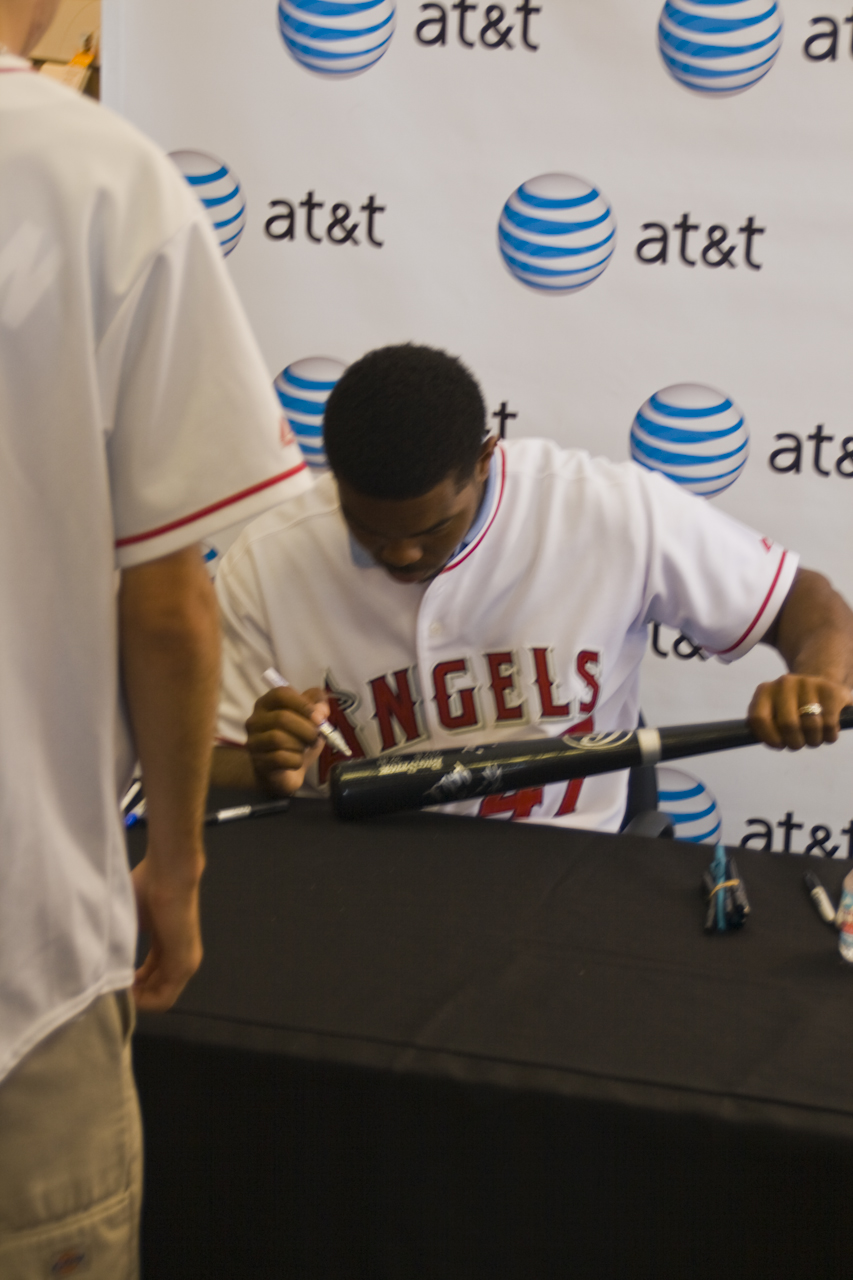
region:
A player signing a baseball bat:
[202, 324, 846, 844]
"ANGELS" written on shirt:
[299, 633, 610, 791]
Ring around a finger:
[784, 681, 832, 729]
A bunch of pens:
[683, 812, 765, 943]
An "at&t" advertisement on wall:
[92, 1, 845, 861]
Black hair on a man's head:
[309, 330, 508, 593]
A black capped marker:
[785, 850, 843, 937]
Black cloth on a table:
[106, 776, 844, 1265]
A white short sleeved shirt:
[0, 37, 326, 1084]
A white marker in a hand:
[229, 648, 366, 810]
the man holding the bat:
[227, 334, 850, 876]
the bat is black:
[314, 680, 850, 840]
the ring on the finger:
[790, 699, 826, 718]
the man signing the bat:
[188, 310, 850, 846]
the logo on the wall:
[492, 147, 777, 311]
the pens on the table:
[695, 836, 775, 929]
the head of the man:
[310, 327, 524, 586]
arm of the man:
[630, 472, 850, 733]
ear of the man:
[470, 426, 512, 494]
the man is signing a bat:
[197, 344, 851, 820]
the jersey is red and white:
[209, 440, 801, 834]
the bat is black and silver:
[326, 695, 849, 816]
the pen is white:
[261, 665, 352, 760]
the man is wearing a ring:
[202, 339, 849, 809]